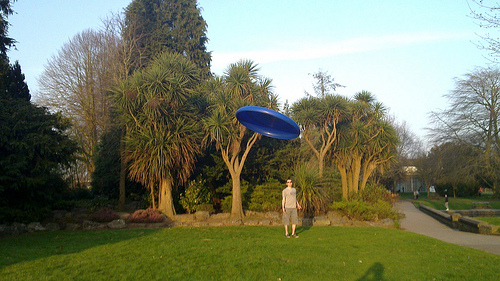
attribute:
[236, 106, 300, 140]
frisbee — blue, flying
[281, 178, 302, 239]
man — standing, watching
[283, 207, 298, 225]
shorts — grey, baggy, gray, dark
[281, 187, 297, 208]
shirt — grey, gray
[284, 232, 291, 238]
shoe — brown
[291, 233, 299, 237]
shoe — brown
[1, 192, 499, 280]
grass — patch, green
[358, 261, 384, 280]
shadow — photographer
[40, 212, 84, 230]
bed — flowers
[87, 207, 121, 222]
bed — flowers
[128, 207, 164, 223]
bed — flowers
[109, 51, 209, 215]
tree — palm, big, beautiful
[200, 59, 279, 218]
tree — palm, big, beautiful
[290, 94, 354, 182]
tree — palm, big, beautiful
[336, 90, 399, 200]
tree — palm, big, beautiful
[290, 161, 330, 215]
tree — palm, big, beautiful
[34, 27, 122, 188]
tree — leafless, brown, oak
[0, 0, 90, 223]
tree — evergreen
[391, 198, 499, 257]
sidewalk — gray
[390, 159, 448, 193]
residence — background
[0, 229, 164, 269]
shadow — long, early morning, late afternoon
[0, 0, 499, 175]
sky — blue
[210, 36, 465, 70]
cloud — minimal, white, patch, small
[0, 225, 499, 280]
patch — small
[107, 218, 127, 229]
rock — gigantic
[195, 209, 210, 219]
rock — gigantic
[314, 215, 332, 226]
rock — gigantic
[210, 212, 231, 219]
rock — gigantic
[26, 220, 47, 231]
rock — gigantic